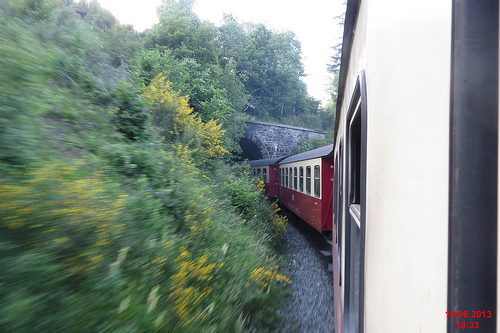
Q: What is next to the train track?
A: Green bushes.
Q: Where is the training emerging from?
A: A tunnel.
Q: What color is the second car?
A: Red.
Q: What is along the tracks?
A: Gravel.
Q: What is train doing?
A: Traveling.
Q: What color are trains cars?
A: Red.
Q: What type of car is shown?
A: Train.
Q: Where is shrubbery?
A: Next to railway.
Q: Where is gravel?
A: Along railway.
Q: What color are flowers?
A: Yellow.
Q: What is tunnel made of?
A: Brick.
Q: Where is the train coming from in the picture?
A: A tunnel.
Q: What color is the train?
A: Red.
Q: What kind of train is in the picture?
A: Passenger train.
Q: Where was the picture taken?
A: On a train.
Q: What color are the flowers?
A: Yellow.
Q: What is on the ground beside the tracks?
A: Gravel.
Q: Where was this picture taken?
A: Out the window.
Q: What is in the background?
A: Tunnel.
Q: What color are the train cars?
A: Red and White.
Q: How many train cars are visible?
A: 3.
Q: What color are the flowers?
A: Yellow.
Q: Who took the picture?
A: Passenger.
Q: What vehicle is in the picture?
A: Train.